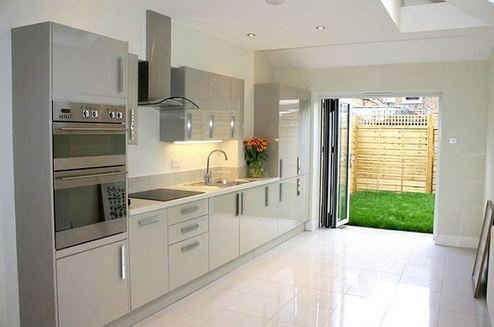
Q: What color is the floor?
A: White.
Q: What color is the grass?
A: Green.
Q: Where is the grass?
A: Through the door.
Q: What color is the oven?
A: Grey.